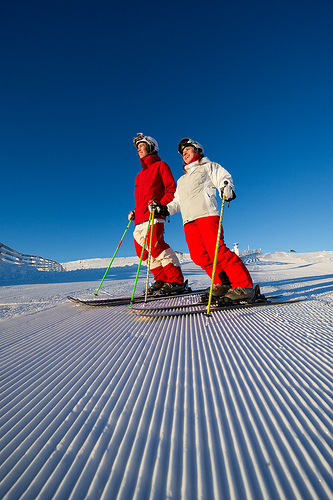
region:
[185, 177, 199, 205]
man wearing white coat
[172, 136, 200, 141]
man wearing black and white helmet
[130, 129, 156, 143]
white helmet on mans head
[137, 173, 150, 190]
man wears red coat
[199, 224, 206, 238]
man wearing red pants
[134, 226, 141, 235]
white patch on pants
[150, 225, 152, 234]
red patch on pants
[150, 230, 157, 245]
silver zipper on pants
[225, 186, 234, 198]
man wearing white gloves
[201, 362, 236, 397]
white snow on ground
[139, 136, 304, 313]
a skier going down hill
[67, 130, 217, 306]
a skier going down hill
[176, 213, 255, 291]
a pair of red snow pants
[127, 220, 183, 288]
a pair of red and white snow pants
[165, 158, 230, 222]
a white winter coat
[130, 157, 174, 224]
a red winter coat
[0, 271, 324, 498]
tracks in snow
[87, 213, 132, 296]
a lime green ski pole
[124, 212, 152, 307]
a lime green ski pole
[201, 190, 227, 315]
a yellow ski pole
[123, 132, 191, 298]
Person in the red jacket.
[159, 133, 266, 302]
Person in the white jacket.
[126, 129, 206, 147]
Helmets worn by the people.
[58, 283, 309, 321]
Skis worn by the people.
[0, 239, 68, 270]
A wooden fence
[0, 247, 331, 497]
The Snow.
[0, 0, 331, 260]
The sky.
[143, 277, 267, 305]
Snow boots worn by them.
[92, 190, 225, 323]
Ski poles held by the skiiers.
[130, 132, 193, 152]
Goggles on the helmets.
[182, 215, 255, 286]
red pants on a man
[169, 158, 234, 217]
a white coat on a man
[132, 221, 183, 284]
red and white pants on a man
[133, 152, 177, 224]
a red coat on a man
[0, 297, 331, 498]
grooves scraped into the snow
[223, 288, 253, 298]
a gray ski boot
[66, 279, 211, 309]
skis on a man's feet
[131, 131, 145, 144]
goggles on a helmet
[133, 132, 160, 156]
a white helmet on a man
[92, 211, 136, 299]
a green ski pole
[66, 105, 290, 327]
two skiers standing in ridges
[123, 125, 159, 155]
helmet on skier's head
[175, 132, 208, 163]
helmet on skier's head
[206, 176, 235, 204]
gloves on skier's hand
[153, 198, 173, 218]
gloves on skier's hand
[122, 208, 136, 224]
gloves on skier's hand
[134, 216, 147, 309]
ski poles in hands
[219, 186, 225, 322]
ski poles in hands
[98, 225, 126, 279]
ski poles in hands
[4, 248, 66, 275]
fence along field of snow